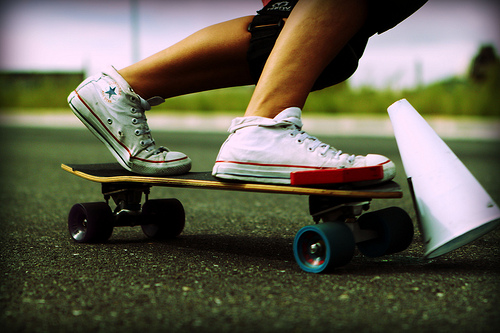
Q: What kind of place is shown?
A: It is a street.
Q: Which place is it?
A: It is a street.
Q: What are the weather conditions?
A: It is overcast.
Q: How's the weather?
A: It is overcast.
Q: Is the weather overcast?
A: Yes, it is overcast.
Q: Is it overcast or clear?
A: It is overcast.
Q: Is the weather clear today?
A: No, it is overcast.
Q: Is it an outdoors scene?
A: Yes, it is outdoors.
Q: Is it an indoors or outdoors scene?
A: It is outdoors.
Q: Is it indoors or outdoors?
A: It is outdoors.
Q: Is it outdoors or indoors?
A: It is outdoors.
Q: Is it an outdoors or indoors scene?
A: It is outdoors.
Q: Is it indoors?
A: No, it is outdoors.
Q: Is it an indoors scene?
A: No, it is outdoors.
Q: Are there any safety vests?
A: No, there are no safety vests.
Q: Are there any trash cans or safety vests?
A: No, there are no safety vests or trash cans.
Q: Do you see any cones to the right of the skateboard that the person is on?
A: Yes, there is a cone to the right of the skateboard.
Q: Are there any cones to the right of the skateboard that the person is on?
A: Yes, there is a cone to the right of the skateboard.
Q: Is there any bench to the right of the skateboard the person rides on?
A: No, there is a cone to the right of the skateboard.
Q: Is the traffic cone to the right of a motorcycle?
A: No, the traffic cone is to the right of the skateboard.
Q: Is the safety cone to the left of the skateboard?
A: No, the safety cone is to the right of the skateboard.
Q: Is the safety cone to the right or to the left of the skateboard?
A: The safety cone is to the right of the skateboard.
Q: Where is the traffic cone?
A: The traffic cone is on the street.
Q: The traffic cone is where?
A: The traffic cone is on the street.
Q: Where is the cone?
A: The traffic cone is on the street.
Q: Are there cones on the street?
A: Yes, there is a cone on the street.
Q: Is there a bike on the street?
A: No, there is a cone on the street.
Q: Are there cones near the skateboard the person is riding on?
A: Yes, there is a cone near the skateboard.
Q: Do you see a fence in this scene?
A: No, there are no fences.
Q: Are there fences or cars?
A: No, there are no fences or cars.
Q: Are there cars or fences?
A: No, there are no fences or cars.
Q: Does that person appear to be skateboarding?
A: Yes, the person is skateboarding.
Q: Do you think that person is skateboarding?
A: Yes, the person is skateboarding.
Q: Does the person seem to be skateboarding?
A: Yes, the person is skateboarding.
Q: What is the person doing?
A: The person is skateboarding.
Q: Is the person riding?
A: No, the person is skateboarding.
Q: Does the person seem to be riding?
A: No, the person is skateboarding.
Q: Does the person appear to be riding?
A: No, the person is skateboarding.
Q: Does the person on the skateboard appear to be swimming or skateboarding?
A: The person is skateboarding.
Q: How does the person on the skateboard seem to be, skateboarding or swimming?
A: The person is skateboarding.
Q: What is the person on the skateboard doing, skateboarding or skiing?
A: The person is skateboarding.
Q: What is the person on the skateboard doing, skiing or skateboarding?
A: The person is skateboarding.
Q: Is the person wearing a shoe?
A: Yes, the person is wearing a shoe.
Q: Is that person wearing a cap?
A: No, the person is wearing a shoe.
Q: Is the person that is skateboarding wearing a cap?
A: No, the person is wearing a shoe.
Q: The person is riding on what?
A: The person is riding on a skateboard.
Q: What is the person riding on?
A: The person is riding on a skateboard.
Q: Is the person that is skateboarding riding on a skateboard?
A: Yes, the person is riding on a skateboard.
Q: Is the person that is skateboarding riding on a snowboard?
A: No, the person is riding on a skateboard.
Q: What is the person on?
A: The person is on the skateboard.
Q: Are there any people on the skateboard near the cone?
A: Yes, there is a person on the skateboard.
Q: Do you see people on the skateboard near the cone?
A: Yes, there is a person on the skateboard.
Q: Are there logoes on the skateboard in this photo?
A: No, there is a person on the skateboard.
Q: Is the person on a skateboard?
A: Yes, the person is on a skateboard.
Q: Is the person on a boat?
A: No, the person is on a skateboard.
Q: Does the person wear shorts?
A: Yes, the person wears shorts.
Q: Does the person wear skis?
A: No, the person wears shorts.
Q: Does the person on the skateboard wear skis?
A: No, the person wears shorts.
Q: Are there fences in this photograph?
A: No, there are no fences.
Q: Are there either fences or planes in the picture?
A: No, there are no fences or planes.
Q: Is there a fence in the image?
A: No, there are no fences.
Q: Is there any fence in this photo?
A: No, there are no fences.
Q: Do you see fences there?
A: No, there are no fences.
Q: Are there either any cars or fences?
A: No, there are no fences or cars.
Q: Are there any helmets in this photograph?
A: No, there are no helmets.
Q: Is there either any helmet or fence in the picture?
A: No, there are no helmets or fences.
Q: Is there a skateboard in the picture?
A: Yes, there is a skateboard.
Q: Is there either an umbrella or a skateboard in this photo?
A: Yes, there is a skateboard.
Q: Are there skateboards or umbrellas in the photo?
A: Yes, there is a skateboard.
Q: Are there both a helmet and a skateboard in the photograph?
A: No, there is a skateboard but no helmets.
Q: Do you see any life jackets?
A: No, there are no life jackets.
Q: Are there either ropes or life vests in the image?
A: No, there are no life vests or ropes.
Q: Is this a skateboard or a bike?
A: This is a skateboard.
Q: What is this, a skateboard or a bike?
A: This is a skateboard.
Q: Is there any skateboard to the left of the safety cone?
A: Yes, there is a skateboard to the left of the safety cone.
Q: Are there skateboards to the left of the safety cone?
A: Yes, there is a skateboard to the left of the safety cone.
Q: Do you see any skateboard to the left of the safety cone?
A: Yes, there is a skateboard to the left of the safety cone.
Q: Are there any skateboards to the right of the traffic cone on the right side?
A: No, the skateboard is to the left of the cone.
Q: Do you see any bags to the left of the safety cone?
A: No, there is a skateboard to the left of the safety cone.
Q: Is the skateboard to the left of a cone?
A: Yes, the skateboard is to the left of a cone.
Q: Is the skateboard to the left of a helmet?
A: No, the skateboard is to the left of a cone.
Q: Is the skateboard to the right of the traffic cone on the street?
A: No, the skateboard is to the left of the cone.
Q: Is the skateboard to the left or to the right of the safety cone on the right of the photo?
A: The skateboard is to the left of the traffic cone.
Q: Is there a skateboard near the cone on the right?
A: Yes, there is a skateboard near the cone.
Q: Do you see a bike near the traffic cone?
A: No, there is a skateboard near the traffic cone.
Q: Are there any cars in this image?
A: No, there are no cars.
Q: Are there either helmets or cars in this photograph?
A: No, there are no cars or helmets.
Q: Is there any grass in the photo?
A: Yes, there is grass.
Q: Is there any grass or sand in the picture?
A: Yes, there is grass.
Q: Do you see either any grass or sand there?
A: Yes, there is grass.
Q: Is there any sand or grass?
A: Yes, there is grass.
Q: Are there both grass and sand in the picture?
A: No, there is grass but no sand.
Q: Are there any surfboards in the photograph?
A: No, there are no surfboards.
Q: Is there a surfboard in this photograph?
A: No, there are no surfboards.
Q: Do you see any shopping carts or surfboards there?
A: No, there are no surfboards or shopping carts.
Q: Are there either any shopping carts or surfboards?
A: No, there are no surfboards or shopping carts.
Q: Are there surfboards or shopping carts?
A: No, there are no surfboards or shopping carts.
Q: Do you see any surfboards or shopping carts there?
A: No, there are no surfboards or shopping carts.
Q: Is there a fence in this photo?
A: No, there are no fences.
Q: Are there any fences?
A: No, there are no fences.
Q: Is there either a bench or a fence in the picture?
A: No, there are no fences or benches.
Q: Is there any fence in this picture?
A: No, there are no fences.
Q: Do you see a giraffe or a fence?
A: No, there are no fences or giraffes.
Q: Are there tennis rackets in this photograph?
A: No, there are no tennis rackets.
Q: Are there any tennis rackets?
A: No, there are no tennis rackets.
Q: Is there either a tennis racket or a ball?
A: No, there are no rackets or balls.